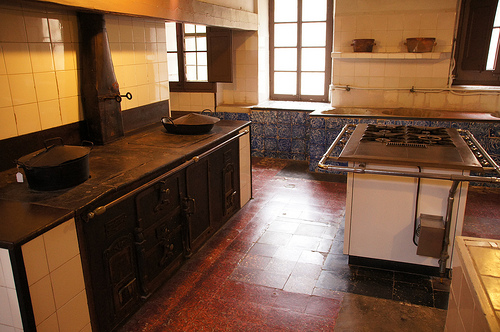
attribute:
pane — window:
[275, 2, 321, 87]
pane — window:
[298, 49, 325, 69]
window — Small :
[299, 1, 324, 21]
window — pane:
[263, 0, 334, 108]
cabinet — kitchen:
[200, 135, 243, 229]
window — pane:
[442, 0, 499, 86]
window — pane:
[158, 22, 212, 85]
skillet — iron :
[162, 107, 221, 137]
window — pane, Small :
[267, 0, 331, 105]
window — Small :
[272, 71, 300, 98]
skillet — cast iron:
[22, 142, 90, 184]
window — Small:
[275, 47, 297, 70]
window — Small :
[300, 20, 327, 45]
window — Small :
[260, 13, 367, 180]